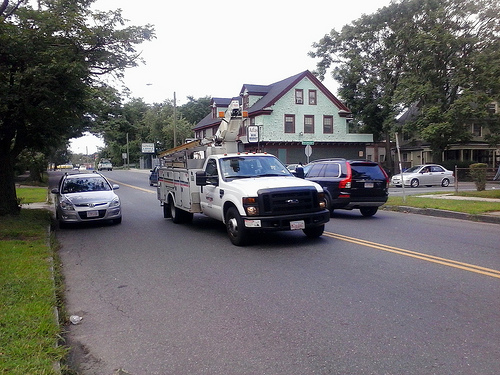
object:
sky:
[188, 13, 252, 65]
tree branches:
[63, 3, 162, 74]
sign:
[170, 124, 237, 200]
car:
[390, 163, 453, 187]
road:
[382, 172, 499, 194]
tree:
[0, 1, 87, 220]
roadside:
[0, 178, 238, 371]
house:
[230, 69, 369, 165]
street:
[52, 167, 499, 371]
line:
[322, 228, 499, 279]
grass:
[0, 181, 61, 374]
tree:
[1, 0, 159, 210]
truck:
[148, 147, 335, 248]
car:
[53, 170, 124, 226]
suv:
[295, 156, 389, 219]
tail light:
[342, 179, 355, 189]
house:
[189, 70, 376, 163]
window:
[293, 87, 305, 106]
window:
[307, 88, 317, 106]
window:
[282, 114, 297, 135]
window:
[303, 114, 317, 134]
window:
[322, 113, 334, 134]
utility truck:
[148, 148, 338, 245]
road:
[53, 167, 499, 372]